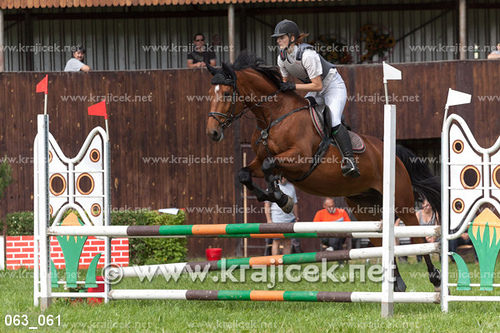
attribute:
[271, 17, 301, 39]
helmet — black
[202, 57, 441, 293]
horse — jumping, brown, black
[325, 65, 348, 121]
pants — white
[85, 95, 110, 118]
flag — red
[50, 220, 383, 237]
stick — striped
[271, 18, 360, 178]
woman — riding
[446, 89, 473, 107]
flag — white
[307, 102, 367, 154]
saddle — brown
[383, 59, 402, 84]
flag — white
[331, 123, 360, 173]
boot — leather, black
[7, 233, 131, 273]
wall — red brick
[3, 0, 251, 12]
wall — dark wood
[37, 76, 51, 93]
flag — red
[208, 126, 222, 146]
nose — brown